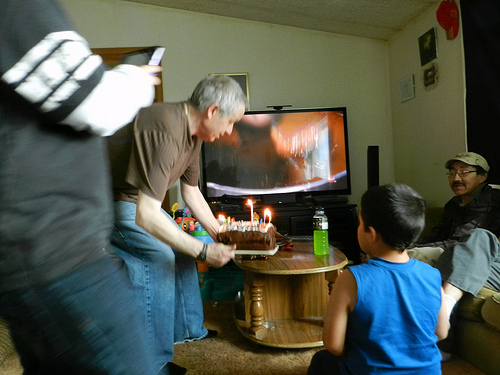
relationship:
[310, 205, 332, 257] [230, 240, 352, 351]
bottle on top of table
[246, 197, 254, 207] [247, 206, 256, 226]
flames on top of candle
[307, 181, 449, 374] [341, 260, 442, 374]
kid wearing shirt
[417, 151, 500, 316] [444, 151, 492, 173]
man wearing hat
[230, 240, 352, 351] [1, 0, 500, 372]
table at center of room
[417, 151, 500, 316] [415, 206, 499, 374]
man sitting sofa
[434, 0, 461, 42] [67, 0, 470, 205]
hat hanging on wall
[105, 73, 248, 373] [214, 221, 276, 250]
man holding cake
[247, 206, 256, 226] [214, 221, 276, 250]
candle on top of cake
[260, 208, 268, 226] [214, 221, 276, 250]
candle on top of cake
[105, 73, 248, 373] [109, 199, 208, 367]
man wearing jeans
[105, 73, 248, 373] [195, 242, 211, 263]
man wearing watch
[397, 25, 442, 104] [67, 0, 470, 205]
pictures hanging on wall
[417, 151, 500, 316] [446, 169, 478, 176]
man wearing glasses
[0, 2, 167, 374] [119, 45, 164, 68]
person holding phone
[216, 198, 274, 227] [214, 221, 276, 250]
candles on top of cake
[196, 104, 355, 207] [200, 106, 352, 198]
tv has flat screen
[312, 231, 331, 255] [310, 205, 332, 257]
green liquid inside of bottle